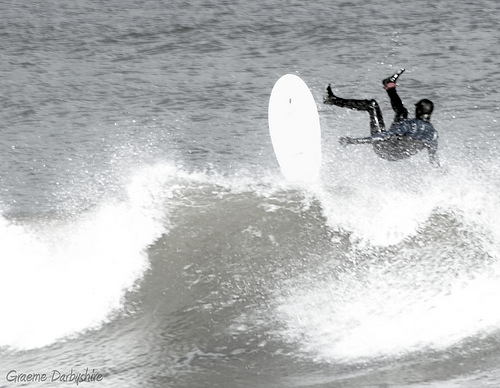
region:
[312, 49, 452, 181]
person wearing a wet suit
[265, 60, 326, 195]
white surf board or body board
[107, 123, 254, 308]
large ocean wave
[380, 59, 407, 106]
right foot of man in water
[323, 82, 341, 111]
left foot of man in water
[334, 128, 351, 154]
left hand of man in ocean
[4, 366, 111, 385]
name of photographer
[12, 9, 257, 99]
small waves in ocean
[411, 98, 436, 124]
head of man in ocean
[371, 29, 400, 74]
over spray of wave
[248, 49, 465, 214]
a man falling off a surfboard into the water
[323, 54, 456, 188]
a man wearing a black wetsuit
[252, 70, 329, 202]
a white surfboard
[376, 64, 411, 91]
a right foot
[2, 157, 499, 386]
a wave of water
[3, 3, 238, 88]
slightly turbid water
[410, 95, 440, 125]
the back of somebody's head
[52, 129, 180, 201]
spray of water droplets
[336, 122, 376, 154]
lower part of left arm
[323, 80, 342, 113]
left foot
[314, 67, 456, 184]
man in wet suit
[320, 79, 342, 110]
the man's left foot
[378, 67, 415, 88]
the man's right foot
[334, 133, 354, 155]
the man's left hand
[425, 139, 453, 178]
the man's right arm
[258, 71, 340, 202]
a white surf board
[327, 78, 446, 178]
a black wet suit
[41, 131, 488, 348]
wave in the water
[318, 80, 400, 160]
the man's left leg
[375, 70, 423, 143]
the man's right leg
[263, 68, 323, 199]
a perpendicular surf board in a wave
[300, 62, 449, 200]
a surfer thrown into the air surfing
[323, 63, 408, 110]
the man has water shoes on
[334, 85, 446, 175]
the man has a full wet suit on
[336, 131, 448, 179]
the surfer is wearing black gloves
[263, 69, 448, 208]
the surfer is wiping out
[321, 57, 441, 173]
the surfer's legs are in the air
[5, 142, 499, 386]
the wave is breaking in different places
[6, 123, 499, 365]
white water is seen on the wave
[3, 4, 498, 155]
the ocean has small swells and ripples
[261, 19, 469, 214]
surfer is flying through air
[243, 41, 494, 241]
surfer fell off surfboard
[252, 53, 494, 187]
white surfboard of surfer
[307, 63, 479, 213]
surfer wearing black shoes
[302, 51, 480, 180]
surfer wearing black pants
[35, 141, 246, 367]
grey waves of water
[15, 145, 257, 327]
foamy caps of waves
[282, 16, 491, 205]
surfer with dark wet hair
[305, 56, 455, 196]
surfer is wet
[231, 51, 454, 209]
surfer is falling into water